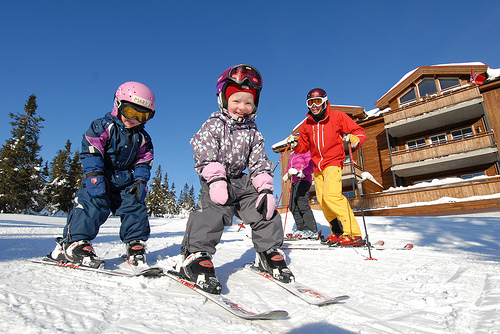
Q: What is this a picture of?
A: People.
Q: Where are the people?
A: On a ski slope.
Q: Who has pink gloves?
A: The girl.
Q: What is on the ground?
A: Snow.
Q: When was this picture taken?
A: During the winter.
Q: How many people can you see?
A: Four.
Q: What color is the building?
A: Tan.